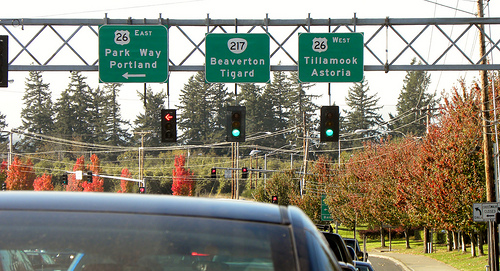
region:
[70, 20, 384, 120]
These are street signs.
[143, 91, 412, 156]
These are traffic signals.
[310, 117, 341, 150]
The sign here is green.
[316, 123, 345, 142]
This signal means go.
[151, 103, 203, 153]
This signal is red.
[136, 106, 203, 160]
This signal means don't turn.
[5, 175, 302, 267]
This is a car.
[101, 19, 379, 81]
These signs are green.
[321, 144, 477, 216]
The leaves on the trees are orange.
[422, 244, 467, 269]
The grass here is green.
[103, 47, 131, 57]
the park in white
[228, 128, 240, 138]
the light is green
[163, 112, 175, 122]
the red light is pointed white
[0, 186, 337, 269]
the hood of a car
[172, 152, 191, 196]
tree has red leaves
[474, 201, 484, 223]
a sign pointing left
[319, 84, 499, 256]
many trees on the side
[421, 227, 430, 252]
the trunk of a tree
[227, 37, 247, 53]
the number 217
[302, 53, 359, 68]
the word Tillamook on the sign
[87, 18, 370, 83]
three green and white signs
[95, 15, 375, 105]
signs on grey poles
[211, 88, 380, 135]
two green traffic lights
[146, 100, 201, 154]
one red traffic light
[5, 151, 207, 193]
red trees under traffic light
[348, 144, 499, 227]
orange trees to right of traffic lights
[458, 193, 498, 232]
white and black sign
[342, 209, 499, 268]
green grass under trees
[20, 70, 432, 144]
tall pines in background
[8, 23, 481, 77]
grey support bars on signposts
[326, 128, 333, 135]
the green traffic light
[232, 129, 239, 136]
the green traffic light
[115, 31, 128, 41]
the 26 on the green sign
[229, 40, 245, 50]
the 217 on the green sign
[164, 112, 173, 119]
the arrow on the traffic light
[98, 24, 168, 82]
the green sign on the left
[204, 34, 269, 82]
the green sign in the middle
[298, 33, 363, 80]
the green sign on the right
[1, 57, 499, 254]
the colorful trees along side the road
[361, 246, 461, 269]
the sidewalk next to the road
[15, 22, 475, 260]
Traffic is moving through a busy street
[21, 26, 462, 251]
Cars are moving through an intersection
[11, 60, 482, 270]
Cars are driving very carefully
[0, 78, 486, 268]
Drivers are enjoying the trip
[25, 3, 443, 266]
Road signs are pointing the way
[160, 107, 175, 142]
A traffic light showing stop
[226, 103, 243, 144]
A traffic light showing green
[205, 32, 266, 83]
The sign showing 217 highway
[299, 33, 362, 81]
The sign showing the way to Tillamook